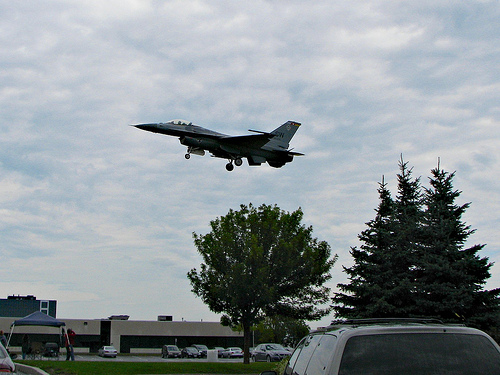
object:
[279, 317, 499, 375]
van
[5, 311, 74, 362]
tent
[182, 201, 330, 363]
tree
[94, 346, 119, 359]
car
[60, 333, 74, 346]
shirt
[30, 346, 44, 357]
shirt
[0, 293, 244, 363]
building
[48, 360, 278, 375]
grass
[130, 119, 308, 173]
airplane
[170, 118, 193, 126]
cockpit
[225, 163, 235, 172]
wheel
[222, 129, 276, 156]
wing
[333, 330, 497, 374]
window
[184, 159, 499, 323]
evergreen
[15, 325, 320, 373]
parking lot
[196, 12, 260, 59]
cloud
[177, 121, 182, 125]
pilot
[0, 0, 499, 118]
sky